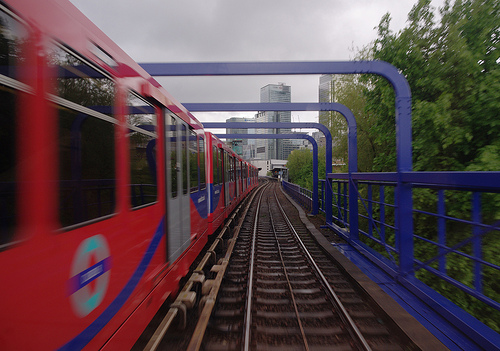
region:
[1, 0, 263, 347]
a large red train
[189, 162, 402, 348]
a set of empty train tracks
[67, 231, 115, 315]
a blurry logo on the side of the train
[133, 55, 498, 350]
blue railing that overlaps the train tracks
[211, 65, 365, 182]
city in the background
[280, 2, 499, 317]
trees bordering the train tracks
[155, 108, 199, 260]
a gray door on the train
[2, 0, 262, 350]
train is moving fast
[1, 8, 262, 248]
train windows are black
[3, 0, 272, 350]
long red train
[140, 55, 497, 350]
purple metal siding on train track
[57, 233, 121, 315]
round grey circle on side of train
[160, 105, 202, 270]
grey train doors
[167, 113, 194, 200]
glass windows on train door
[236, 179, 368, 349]
metal train tracks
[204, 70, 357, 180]
city building beyond train tracks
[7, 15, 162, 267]
blurred train windows in motion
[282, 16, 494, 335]
green foliage bordering train tracks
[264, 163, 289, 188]
dark tunnel opening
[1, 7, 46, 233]
side window on train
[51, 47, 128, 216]
side window on train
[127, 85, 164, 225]
side window on train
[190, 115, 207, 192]
side window on train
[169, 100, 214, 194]
side window on train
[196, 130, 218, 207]
side window on train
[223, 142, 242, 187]
side window on train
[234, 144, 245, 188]
side window on train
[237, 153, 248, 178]
side window on train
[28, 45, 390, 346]
the train is moving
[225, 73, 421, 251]
the buildings are in the distance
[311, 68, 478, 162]
the trees are behind the poles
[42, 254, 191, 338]
a logo is on the train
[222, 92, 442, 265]
the buildings are in the distance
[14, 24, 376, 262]
the train is moving fast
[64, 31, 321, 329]
a train on the tracks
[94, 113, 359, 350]
a train on teh train tracks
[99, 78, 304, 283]
a train moving on the tracks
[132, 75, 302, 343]
a train moving on the train tracks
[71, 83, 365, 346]
a red train on the tracks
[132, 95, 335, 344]
a red train on the train tracks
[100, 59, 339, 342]
a passenger train on the tracks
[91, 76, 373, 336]
a passenger train on the train tracks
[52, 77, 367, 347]
tracks with a train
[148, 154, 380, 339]
tracks with a red train